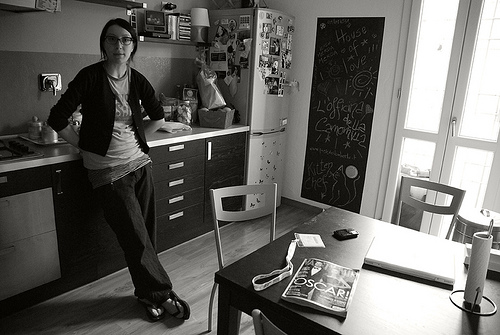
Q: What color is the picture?
A: Black & White.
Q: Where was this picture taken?
A: Kitchen.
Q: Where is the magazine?
A: The table.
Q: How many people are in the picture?
A: One.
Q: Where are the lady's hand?
A: Behind her.